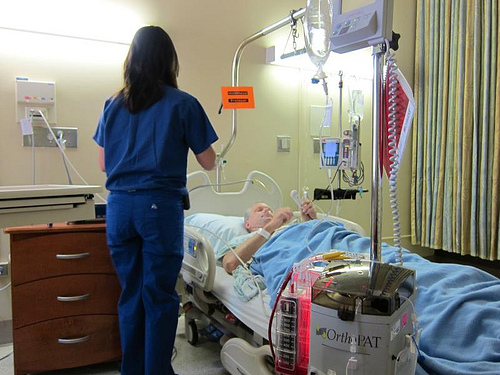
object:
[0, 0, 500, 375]
hospital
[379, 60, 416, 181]
folder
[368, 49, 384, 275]
pole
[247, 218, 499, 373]
blanket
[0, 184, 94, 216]
tray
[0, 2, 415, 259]
wall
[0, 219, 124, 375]
cabinet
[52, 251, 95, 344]
handles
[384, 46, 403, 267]
cable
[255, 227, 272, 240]
bracelet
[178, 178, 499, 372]
bed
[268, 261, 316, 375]
machine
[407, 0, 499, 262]
curtains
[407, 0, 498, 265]
window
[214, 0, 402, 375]
iv machine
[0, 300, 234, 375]
ground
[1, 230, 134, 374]
drawers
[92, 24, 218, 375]
lady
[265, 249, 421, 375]
equipment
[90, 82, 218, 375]
scrub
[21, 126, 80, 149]
socket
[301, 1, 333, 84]
fluid bag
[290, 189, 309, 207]
monitor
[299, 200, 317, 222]
hand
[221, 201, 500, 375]
man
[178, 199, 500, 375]
hospital bed